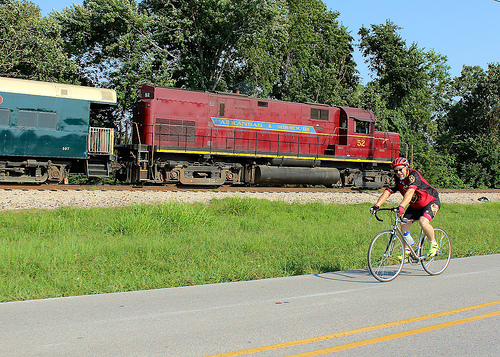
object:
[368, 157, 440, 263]
cyclist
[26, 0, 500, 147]
sky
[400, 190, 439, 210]
wrong construction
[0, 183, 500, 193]
tracks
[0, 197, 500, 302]
grass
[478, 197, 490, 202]
debris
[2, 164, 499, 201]
train track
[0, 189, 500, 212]
rocks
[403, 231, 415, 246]
bottle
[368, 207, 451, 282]
bike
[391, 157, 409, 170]
helmet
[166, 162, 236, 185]
engine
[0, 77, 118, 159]
car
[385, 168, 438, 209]
shirt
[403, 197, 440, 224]
shorts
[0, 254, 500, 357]
road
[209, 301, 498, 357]
line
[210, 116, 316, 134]
banner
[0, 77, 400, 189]
train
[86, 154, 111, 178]
stairs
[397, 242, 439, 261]
shoes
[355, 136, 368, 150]
number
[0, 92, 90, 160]
compartment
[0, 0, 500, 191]
tree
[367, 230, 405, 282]
wheel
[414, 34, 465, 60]
clouds